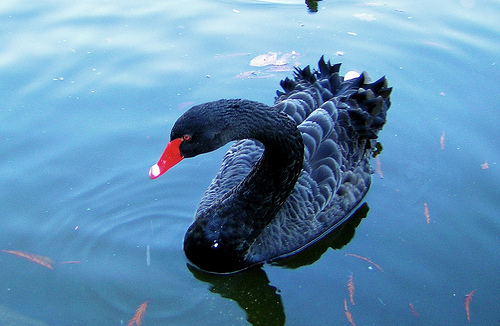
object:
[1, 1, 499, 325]
water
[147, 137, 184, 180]
bill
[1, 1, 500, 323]
lake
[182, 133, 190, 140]
eye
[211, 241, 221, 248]
white debris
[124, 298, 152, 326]
orange fish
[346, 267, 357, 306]
orange fish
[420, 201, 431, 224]
orange fish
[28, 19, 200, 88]
clouds reflection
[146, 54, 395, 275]
black bird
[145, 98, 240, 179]
head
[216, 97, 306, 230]
neck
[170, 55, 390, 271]
feathers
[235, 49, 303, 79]
leaf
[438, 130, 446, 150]
fishes